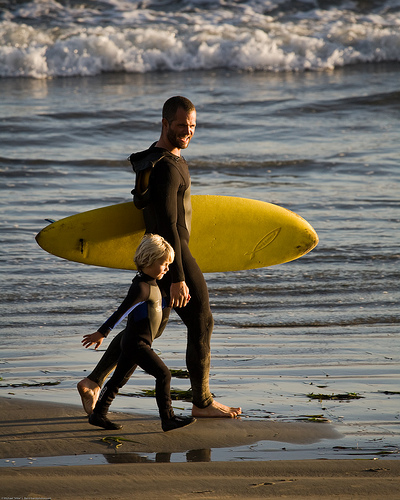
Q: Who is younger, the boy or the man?
A: The boy is younger than the man.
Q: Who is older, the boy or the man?
A: The man is older than the boy.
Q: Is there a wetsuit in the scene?
A: Yes, there is a wetsuit.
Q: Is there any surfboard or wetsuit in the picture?
A: Yes, there is a wetsuit.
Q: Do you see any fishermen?
A: No, there are no fishermen.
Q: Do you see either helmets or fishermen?
A: No, there are no fishermen or helmets.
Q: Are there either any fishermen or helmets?
A: No, there are no fishermen or helmets.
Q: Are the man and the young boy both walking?
A: Yes, both the man and the boy are walking.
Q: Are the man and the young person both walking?
A: Yes, both the man and the boy are walking.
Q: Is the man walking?
A: Yes, the man is walking.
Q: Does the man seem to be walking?
A: Yes, the man is walking.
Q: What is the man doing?
A: The man is walking.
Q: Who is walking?
A: The man is walking.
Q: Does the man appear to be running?
A: No, the man is walking.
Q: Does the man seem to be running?
A: No, the man is walking.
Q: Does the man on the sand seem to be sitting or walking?
A: The man is walking.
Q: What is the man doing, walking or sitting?
A: The man is walking.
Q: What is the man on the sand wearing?
A: The man is wearing a wetsuit.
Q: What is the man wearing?
A: The man is wearing a wetsuit.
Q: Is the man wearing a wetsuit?
A: Yes, the man is wearing a wetsuit.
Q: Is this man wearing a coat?
A: No, the man is wearing a wetsuit.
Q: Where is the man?
A: The man is on the sand.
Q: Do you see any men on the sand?
A: Yes, there is a man on the sand.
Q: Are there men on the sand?
A: Yes, there is a man on the sand.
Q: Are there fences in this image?
A: No, there are no fences.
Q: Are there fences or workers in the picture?
A: No, there are no fences or workers.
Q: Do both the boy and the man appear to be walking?
A: Yes, both the boy and the man are walking.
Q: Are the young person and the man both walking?
A: Yes, both the boy and the man are walking.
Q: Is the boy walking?
A: Yes, the boy is walking.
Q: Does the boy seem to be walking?
A: Yes, the boy is walking.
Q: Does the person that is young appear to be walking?
A: Yes, the boy is walking.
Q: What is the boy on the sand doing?
A: The boy is walking.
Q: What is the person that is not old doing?
A: The boy is walking.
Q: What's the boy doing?
A: The boy is walking.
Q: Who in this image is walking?
A: The boy is walking.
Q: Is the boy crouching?
A: No, the boy is walking.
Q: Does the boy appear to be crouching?
A: No, the boy is walking.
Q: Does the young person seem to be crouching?
A: No, the boy is walking.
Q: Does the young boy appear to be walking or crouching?
A: The boy is walking.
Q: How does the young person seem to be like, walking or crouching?
A: The boy is walking.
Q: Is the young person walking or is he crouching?
A: The boy is walking.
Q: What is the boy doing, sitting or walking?
A: The boy is walking.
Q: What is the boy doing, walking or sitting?
A: The boy is walking.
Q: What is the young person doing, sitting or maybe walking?
A: The boy is walking.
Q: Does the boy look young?
A: Yes, the boy is young.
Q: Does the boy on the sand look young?
A: Yes, the boy is young.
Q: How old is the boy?
A: The boy is young.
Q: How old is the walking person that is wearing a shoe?
A: The boy is young.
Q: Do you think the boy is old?
A: No, the boy is young.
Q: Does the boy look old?
A: No, the boy is young.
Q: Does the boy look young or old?
A: The boy is young.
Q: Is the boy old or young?
A: The boy is young.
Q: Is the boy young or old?
A: The boy is young.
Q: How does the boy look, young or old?
A: The boy is young.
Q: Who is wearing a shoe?
A: The boy is wearing a shoe.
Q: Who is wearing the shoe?
A: The boy is wearing a shoe.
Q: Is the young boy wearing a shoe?
A: Yes, the boy is wearing a shoe.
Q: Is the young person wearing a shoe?
A: Yes, the boy is wearing a shoe.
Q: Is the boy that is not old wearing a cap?
A: No, the boy is wearing a shoe.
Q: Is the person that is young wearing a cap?
A: No, the boy is wearing a shoe.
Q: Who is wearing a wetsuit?
A: The boy is wearing a wetsuit.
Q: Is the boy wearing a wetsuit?
A: Yes, the boy is wearing a wetsuit.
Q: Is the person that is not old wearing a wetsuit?
A: Yes, the boy is wearing a wetsuit.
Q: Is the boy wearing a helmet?
A: No, the boy is wearing a wetsuit.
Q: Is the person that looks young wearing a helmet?
A: No, the boy is wearing a wetsuit.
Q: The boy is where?
A: The boy is on the sand.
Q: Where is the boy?
A: The boy is on the sand.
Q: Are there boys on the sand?
A: Yes, there is a boy on the sand.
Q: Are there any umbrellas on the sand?
A: No, there is a boy on the sand.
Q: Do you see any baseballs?
A: No, there are no baseballs.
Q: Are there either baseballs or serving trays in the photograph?
A: No, there are no baseballs or serving trays.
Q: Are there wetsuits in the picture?
A: Yes, there is a wetsuit.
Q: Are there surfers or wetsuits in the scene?
A: Yes, there is a wetsuit.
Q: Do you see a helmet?
A: No, there are no helmets.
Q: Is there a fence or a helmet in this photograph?
A: No, there are no helmets or fences.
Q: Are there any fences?
A: No, there are no fences.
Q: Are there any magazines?
A: No, there are no magazines.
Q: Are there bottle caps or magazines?
A: No, there are no magazines or bottle caps.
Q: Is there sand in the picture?
A: Yes, there is sand.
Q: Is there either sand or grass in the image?
A: Yes, there is sand.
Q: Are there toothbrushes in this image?
A: No, there are no toothbrushes.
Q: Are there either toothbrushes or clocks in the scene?
A: No, there are no toothbrushes or clocks.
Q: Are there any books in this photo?
A: No, there are no books.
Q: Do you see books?
A: No, there are no books.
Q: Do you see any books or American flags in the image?
A: No, there are no books or American flags.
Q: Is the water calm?
A: Yes, the water is calm.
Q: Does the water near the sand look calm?
A: Yes, the water is calm.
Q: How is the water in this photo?
A: The water is calm.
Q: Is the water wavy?
A: No, the water is calm.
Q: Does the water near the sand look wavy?
A: No, the water is calm.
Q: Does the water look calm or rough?
A: The water is calm.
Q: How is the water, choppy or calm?
A: The water is calm.